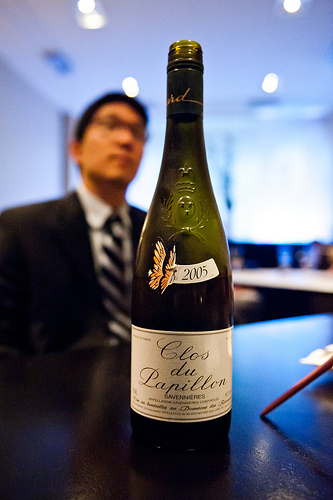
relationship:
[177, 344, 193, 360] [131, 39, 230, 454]
black letter on bottle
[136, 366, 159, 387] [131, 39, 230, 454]
letter on bottle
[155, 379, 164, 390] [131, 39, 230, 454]
letter on bottle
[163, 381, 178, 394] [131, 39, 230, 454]
letter on bottle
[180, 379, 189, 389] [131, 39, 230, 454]
letter on bottle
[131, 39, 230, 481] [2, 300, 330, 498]
bottle on table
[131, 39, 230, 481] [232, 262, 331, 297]
bottle on table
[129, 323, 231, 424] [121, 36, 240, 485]
label on bottle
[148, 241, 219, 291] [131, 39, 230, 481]
label on bottle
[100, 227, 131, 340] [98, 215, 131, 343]
stripe on tie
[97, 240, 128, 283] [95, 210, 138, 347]
stripe on tie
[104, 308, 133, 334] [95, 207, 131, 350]
stripe on tie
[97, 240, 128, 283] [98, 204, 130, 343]
stripe on tie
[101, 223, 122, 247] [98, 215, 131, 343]
stripe on tie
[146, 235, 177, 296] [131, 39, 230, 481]
butterfly on bottle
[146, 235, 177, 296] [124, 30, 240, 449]
butterfly on bottle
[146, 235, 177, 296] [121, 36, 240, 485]
butterfly on bottle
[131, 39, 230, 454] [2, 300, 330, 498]
bottle on table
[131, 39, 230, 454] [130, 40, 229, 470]
bottle of wine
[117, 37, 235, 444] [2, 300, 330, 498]
wine on table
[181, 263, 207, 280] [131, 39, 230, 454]
year 2005 on bottle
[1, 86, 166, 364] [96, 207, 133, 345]
man wearing tie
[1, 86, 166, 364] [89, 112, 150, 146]
man wearing glasses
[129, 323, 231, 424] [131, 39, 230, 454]
label on bottle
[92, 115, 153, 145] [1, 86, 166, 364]
glasses on man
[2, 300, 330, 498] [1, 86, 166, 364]
table in front of man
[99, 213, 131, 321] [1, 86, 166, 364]
tie on man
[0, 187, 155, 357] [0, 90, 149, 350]
suit on person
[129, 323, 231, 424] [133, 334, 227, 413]
label with lettering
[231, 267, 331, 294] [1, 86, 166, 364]
table behind man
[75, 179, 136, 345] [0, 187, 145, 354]
shirt under jacket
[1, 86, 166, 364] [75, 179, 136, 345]
man wearing shirt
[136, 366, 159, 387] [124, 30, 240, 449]
letter on bottle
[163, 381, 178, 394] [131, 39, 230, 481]
letter on bottle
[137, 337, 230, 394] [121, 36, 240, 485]
black letter on bottle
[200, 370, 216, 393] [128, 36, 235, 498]
letter on bottle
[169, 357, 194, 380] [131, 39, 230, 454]
letter on bottle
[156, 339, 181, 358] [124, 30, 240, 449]
letter on bottle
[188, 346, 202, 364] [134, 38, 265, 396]
letter on bottle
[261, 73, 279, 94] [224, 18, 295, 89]
lights on ceiling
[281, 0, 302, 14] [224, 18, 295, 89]
lights on ceiling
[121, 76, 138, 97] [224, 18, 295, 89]
lights on ceiling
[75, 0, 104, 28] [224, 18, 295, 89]
lights on ceiling